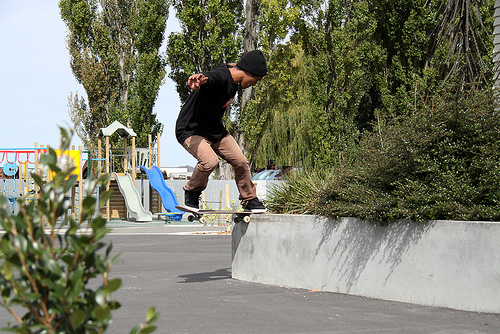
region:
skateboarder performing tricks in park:
[151, 51, 286, 227]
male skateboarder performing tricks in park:
[131, 51, 281, 227]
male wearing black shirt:
[202, 71, 232, 128]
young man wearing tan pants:
[187, 150, 250, 191]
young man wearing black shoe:
[177, 188, 193, 206]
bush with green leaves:
[25, 186, 118, 333]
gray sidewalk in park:
[139, 246, 220, 293]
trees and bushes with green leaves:
[310, 32, 471, 196]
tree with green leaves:
[83, 13, 144, 105]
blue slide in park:
[140, 165, 173, 211]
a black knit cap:
[235, 48, 267, 75]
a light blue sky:
[12, 28, 61, 62]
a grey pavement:
[183, 297, 275, 319]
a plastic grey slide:
[108, 168, 153, 219]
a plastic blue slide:
[137, 163, 187, 216]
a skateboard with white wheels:
[175, 203, 269, 223]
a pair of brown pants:
[183, 134, 258, 197]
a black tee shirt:
[173, 61, 240, 144]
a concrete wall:
[229, 213, 499, 314]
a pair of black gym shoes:
[180, 186, 267, 212]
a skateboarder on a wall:
[168, 43, 270, 225]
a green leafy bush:
[3, 121, 172, 328]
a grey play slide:
[110, 171, 153, 226]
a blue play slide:
[138, 154, 184, 219]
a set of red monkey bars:
[0, 144, 49, 163]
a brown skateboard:
[173, 201, 265, 226]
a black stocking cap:
[231, 46, 271, 81]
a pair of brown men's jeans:
[175, 129, 261, 200]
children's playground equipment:
[1, 119, 188, 227]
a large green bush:
[274, 86, 496, 216]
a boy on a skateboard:
[163, 44, 292, 223]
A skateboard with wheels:
[168, 202, 268, 224]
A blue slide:
[142, 157, 184, 230]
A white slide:
[110, 168, 152, 226]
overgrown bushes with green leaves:
[342, 75, 489, 218]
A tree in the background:
[62, 8, 167, 118]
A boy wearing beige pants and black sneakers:
[182, 131, 272, 218]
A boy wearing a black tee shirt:
[170, 67, 235, 139]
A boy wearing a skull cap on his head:
[237, 40, 272, 97]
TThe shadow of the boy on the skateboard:
[171, 257, 232, 287]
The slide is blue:
[133, 159, 201, 222]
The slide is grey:
[104, 166, 160, 236]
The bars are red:
[0, 133, 58, 166]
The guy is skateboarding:
[150, 36, 302, 231]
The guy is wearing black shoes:
[170, 36, 311, 222]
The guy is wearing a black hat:
[162, 32, 297, 223]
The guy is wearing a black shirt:
[153, 24, 321, 242]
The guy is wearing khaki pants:
[148, 33, 287, 232]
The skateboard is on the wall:
[174, 198, 301, 234]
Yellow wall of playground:
[43, 147, 81, 177]